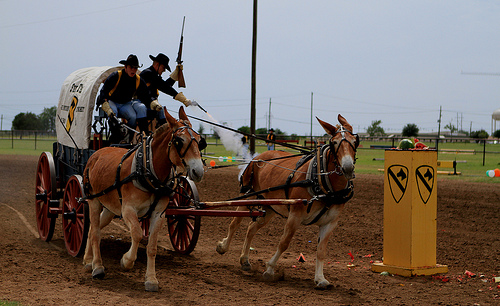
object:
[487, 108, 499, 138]
water tower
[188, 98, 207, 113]
gun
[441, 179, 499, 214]
ground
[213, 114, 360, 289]
horse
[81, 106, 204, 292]
horse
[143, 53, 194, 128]
man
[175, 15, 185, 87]
gun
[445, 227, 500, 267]
ground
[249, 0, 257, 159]
pole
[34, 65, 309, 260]
covered wagon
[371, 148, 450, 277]
pole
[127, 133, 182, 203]
harness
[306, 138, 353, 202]
harness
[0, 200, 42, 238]
track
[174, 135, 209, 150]
blinders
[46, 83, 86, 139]
logo wagon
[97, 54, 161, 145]
man